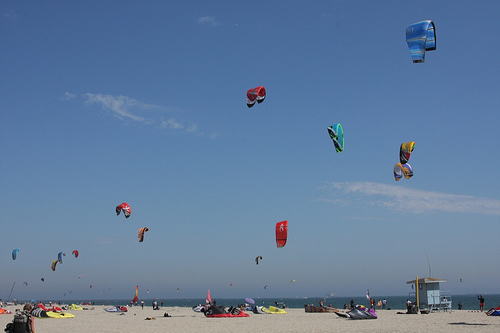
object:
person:
[23, 303, 67, 320]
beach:
[2, 303, 499, 333]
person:
[204, 305, 241, 315]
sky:
[1, 3, 499, 299]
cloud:
[319, 179, 499, 221]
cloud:
[63, 88, 214, 141]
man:
[5, 303, 37, 330]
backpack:
[12, 312, 31, 332]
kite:
[275, 220, 288, 248]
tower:
[405, 275, 453, 315]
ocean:
[5, 294, 499, 312]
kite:
[403, 17, 437, 65]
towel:
[205, 312, 251, 319]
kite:
[392, 139, 417, 182]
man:
[475, 292, 486, 311]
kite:
[459, 279, 464, 284]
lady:
[22, 304, 61, 320]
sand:
[0, 304, 499, 333]